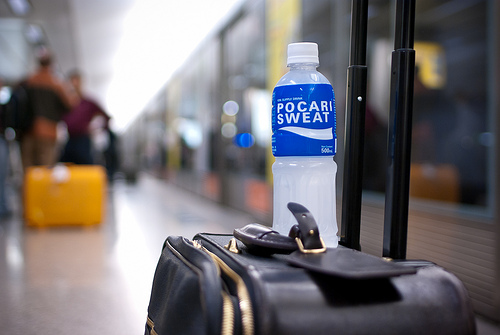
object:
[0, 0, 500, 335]
train station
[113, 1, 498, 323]
train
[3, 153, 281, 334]
platform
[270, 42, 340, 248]
water bottle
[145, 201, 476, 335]
suitcase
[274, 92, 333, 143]
label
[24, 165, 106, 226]
suitcase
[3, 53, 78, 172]
man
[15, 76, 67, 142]
jacket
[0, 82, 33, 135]
backpack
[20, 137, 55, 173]
pants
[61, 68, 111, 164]
person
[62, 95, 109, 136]
shirt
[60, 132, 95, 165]
pants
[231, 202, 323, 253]
handle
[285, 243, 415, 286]
tag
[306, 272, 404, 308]
shadow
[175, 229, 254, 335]
zippers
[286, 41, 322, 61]
bottle cap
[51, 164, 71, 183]
luggage tag